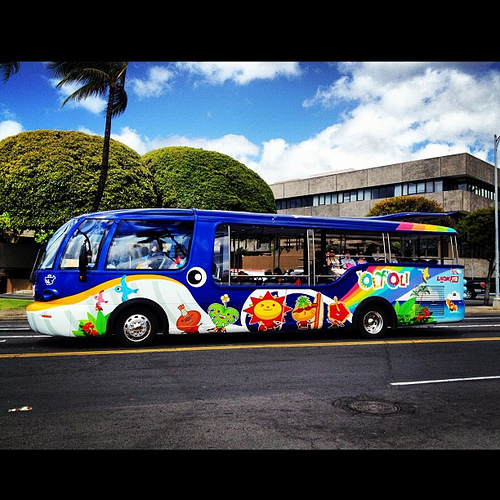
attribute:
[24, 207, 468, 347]
bus — colorful, blue, painted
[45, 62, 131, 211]
tree — blowing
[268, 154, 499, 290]
building — grey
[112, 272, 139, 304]
bird — blue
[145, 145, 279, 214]
tree — round, green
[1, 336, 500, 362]
line — yellow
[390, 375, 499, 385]
line — white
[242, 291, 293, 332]
sun — yellow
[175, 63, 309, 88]
cloud — white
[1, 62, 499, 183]
sky — blue, cloudy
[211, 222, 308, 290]
window — large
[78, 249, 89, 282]
mirror — black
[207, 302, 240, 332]
heart — green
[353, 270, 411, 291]
word — colorful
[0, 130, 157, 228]
bush — large